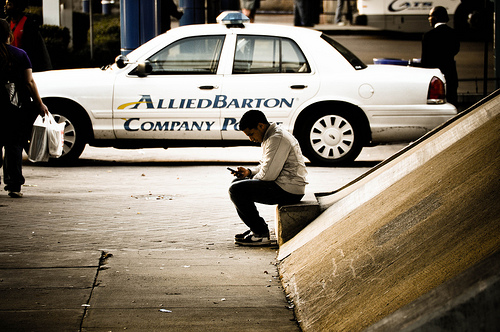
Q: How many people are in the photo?
A: 2.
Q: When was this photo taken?
A: During the day.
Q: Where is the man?
A: Sitting on a step.